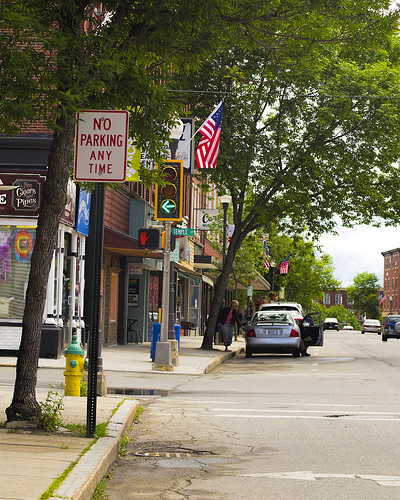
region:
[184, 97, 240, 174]
An American flag hanging over a street.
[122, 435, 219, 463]
A manhole cover.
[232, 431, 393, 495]
An arrow in the street indicating a left turn.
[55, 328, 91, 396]
A yellow and green fire hydrant.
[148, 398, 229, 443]
Several cracks in the road.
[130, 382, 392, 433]
White crosswalk stripes.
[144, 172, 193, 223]
Green arrow on a traffic light.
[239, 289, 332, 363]
a foot stepping out of a car.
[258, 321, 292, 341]
The licence of a car.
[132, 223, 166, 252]
Red hand showing the don't walk signal.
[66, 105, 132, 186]
no parking anytime street sign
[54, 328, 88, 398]
green and yellow fire hydrant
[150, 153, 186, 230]
green left turn arrow signal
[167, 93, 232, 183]
red, white, and blue american flag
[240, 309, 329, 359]
parked car with open passenger door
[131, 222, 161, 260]
crosswalk signal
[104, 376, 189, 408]
puddle in middle of street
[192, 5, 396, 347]
tall green leaning tree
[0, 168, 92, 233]
corner storefront signs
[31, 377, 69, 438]
weeds growing at the tree stump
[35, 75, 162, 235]
No parking sign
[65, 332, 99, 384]
A fire hydrant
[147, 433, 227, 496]
A manhole on the street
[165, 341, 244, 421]
A street curb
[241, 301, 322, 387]
A car parked on the street curb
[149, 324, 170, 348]
A light post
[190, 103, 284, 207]
A flag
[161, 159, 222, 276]
A traffic light with a green arrow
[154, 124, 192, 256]
An intersection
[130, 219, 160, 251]
A red hand light for not walking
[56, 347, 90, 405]
fire hydrant is yellow and green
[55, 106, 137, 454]
A NO PARKING sign on the sidewalk.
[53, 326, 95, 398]
Yellow and green fire hydrant on the street corner.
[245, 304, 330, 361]
Car parked along the road.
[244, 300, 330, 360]
Silver car with an open door.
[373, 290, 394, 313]
A flag on the outside of a building.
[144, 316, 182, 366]
Blue trashcan on the corner.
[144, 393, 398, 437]
A crosswalk on the road.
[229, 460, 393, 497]
White arrow painted on the road pointing left.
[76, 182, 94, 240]
Blue business sign on the outside of a building.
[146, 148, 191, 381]
A stoplight with a green arrow.